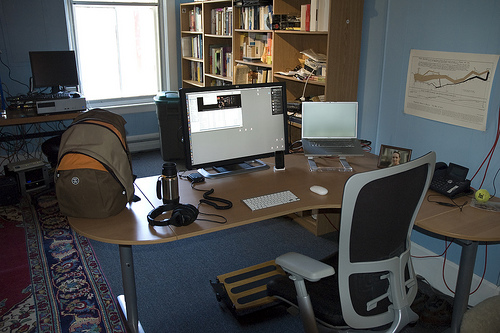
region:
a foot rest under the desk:
[207, 237, 318, 321]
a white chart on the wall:
[397, 32, 494, 142]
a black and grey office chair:
[272, 152, 447, 331]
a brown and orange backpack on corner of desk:
[51, 92, 173, 235]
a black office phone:
[416, 140, 477, 209]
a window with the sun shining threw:
[59, 3, 206, 123]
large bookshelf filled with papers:
[178, 3, 374, 152]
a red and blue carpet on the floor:
[1, 178, 167, 331]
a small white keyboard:
[234, 178, 304, 218]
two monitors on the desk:
[169, 74, 406, 204]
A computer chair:
[264, 148, 453, 330]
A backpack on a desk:
[53, 106, 139, 223]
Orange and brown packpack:
[56, 103, 137, 223]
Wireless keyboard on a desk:
[243, 191, 301, 213]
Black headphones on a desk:
[145, 197, 232, 229]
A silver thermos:
[154, 160, 184, 206]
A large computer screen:
[177, 85, 290, 176]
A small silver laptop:
[303, 93, 365, 160]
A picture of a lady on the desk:
[376, 141, 412, 174]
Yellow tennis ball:
[477, 186, 491, 203]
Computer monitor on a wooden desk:
[178, 84, 290, 170]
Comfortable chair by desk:
[275, 150, 440, 331]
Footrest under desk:
[213, 259, 303, 321]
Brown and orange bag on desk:
[50, 107, 140, 218]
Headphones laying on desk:
[143, 200, 198, 230]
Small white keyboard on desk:
[242, 189, 299, 215]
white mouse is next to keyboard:
[309, 180, 329, 201]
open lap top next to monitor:
[299, 92, 365, 167]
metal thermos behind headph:
[155, 161, 185, 204]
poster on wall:
[402, 65, 495, 133]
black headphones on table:
[147, 198, 201, 230]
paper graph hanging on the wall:
[404, 48, 496, 133]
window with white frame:
[66, 1, 176, 111]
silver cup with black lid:
[156, 161, 181, 203]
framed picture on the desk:
[377, 143, 411, 169]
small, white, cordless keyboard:
[242, 187, 300, 212]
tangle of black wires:
[3, 123, 64, 163]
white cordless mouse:
[308, 183, 328, 194]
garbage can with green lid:
[151, 90, 184, 159]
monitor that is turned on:
[180, 83, 289, 165]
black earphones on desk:
[142, 200, 200, 228]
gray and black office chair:
[267, 143, 434, 326]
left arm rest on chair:
[270, 246, 340, 284]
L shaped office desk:
[40, 145, 495, 290]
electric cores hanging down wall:
[402, 226, 493, 301]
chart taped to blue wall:
[391, 35, 496, 130]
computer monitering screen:
[177, 82, 287, 167]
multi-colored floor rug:
[17, 233, 140, 329]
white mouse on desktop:
[305, 180, 330, 196]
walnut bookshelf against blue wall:
[266, 4, 361, 142]